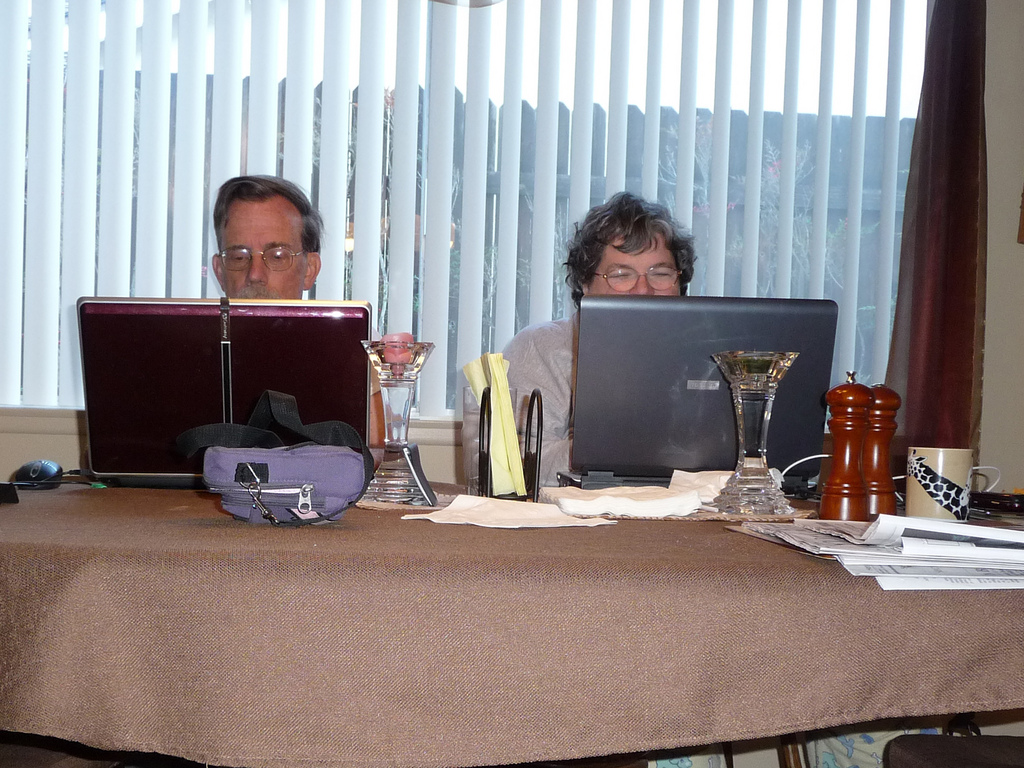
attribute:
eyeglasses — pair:
[573, 246, 693, 295]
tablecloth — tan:
[19, 528, 1002, 715]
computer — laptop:
[53, 240, 391, 513]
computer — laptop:
[558, 277, 881, 511]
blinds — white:
[0, 0, 940, 433]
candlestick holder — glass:
[350, 338, 437, 503]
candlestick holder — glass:
[703, 345, 803, 525]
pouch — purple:
[201, 438, 370, 532]